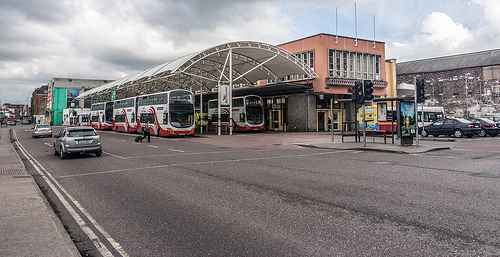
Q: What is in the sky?
A: Cloud cover in sky.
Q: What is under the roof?
A: Busses parked under roof.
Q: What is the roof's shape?
A: Long curved gray roof.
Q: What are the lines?
A: Double white lines on asphalt.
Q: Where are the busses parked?
A: At a station.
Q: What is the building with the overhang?
A: A bus station.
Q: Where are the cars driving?
A: On the road.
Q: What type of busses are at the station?
A: Doubledecker busses.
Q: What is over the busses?
A: A protecting roof.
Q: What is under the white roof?
A: A row of buses.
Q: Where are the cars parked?
A: In the lot by the bus stop.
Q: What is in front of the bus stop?
A: A black traffic light.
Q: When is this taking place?
A: Daytime.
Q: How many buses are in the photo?
A: Two.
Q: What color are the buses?
A: Red and white.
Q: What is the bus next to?
A: Bus stop.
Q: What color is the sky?
A: Blue and white.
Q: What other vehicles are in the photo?
A: Cars.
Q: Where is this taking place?
A: At a bus stop.